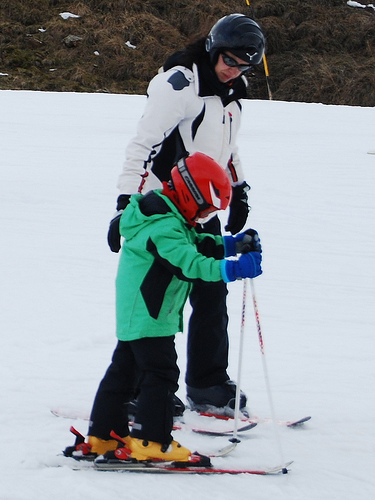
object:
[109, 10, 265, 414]
woman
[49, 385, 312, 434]
skis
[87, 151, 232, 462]
child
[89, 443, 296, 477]
skis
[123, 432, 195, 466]
boots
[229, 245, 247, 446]
ski poles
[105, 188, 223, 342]
coat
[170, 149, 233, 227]
helmet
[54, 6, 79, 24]
snow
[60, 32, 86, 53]
rock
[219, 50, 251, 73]
sunglasses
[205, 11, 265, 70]
helmet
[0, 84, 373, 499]
ground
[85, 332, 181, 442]
ski pants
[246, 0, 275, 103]
pole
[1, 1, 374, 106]
grass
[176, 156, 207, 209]
stripes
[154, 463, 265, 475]
stripe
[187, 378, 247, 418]
snow shoes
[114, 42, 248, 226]
coat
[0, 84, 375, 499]
snow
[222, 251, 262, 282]
right glove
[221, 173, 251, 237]
left glove